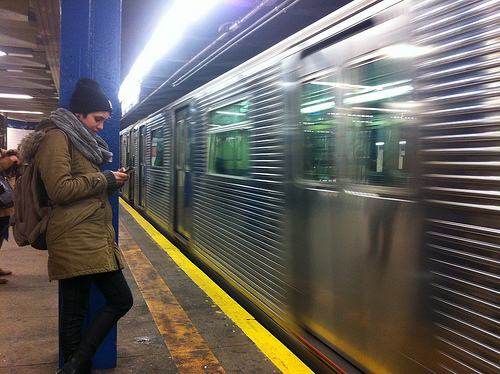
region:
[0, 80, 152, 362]
a girl who is texting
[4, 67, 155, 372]
young woman who is texting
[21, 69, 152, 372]
girl leaning against pole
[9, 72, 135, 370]
young woman leaning against pole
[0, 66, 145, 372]
girl wearing a backpack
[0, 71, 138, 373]
young woman wearing a backpack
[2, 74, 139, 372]
girl wearing a sock hat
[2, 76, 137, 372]
young woman wearing a sock hat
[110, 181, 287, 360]
yellow line near train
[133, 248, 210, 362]
dirty yellow line on concrete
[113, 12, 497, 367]
Moving train passing through station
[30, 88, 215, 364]
Girl in brown coat standing at train station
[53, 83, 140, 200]
Girl in knitted hat looking at cell phone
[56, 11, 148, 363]
Blue pole to next to girl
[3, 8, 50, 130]
Fluorescent lights in ceiling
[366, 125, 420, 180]
View of the outside of other side of train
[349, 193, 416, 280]
Reflection of person on train wall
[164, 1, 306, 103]
Electric cables above subway train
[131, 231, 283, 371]
Two yellow lines near edge of subway platform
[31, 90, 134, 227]
Girl wearing thick grey scarf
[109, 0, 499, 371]
A silver train.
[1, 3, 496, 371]
A subway station.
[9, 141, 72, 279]
A brown colored bookbag.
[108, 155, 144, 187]
A cellphone.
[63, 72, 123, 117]
A black tobogan.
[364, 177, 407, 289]
A reflection in the side of the train.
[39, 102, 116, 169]
A dark colored scarf.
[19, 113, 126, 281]
A brown coat with fur on the hood.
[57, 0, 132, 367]
A blue pole.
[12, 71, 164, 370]
A lady looking at a cellphone.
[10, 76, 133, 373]
A woman texting on cell phone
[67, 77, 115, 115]
A blue cap on the woman's head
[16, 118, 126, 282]
a green coat with hoodie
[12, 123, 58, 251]
A gray back pack on woman's back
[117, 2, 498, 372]
A silver subway train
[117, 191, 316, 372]
a yellow safety line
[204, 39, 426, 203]
three large glass windows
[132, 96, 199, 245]
two subway train doors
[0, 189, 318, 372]
a gray concrete walkway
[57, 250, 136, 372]
a woman with blue jean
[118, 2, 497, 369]
The train is moving fast.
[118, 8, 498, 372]
The train is silver.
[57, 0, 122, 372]
The pole is blue.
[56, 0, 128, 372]
The pole is straight.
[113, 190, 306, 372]
Yellow lines painted on concrete.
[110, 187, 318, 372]
The painted lines are straight.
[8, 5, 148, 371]
Girl is leaning against pole.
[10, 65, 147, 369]
The girl is looking at her phone.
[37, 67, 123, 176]
Girl is wearing earring.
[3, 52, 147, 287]
Girl is carrying a backpack.